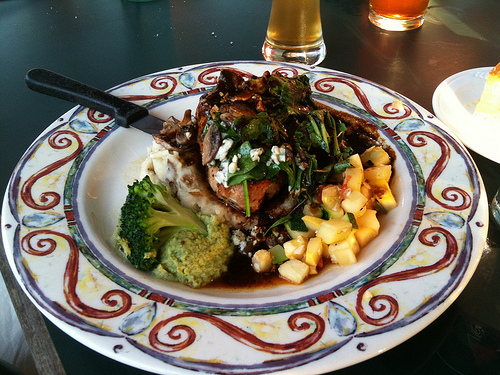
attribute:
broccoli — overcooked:
[115, 180, 210, 267]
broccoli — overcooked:
[157, 218, 234, 290]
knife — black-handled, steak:
[21, 61, 165, 143]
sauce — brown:
[211, 234, 286, 294]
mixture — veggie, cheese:
[112, 68, 397, 287]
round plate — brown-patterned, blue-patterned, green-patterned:
[55, 96, 364, 316]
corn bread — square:
[473, 60, 496, 127]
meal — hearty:
[72, 91, 413, 279]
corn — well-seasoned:
[341, 190, 368, 214]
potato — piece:
[317, 217, 354, 241]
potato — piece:
[329, 245, 353, 265]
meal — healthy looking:
[109, 64, 398, 296]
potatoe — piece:
[256, 247, 274, 269]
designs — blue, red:
[2, 53, 499, 373]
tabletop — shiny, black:
[91, 10, 213, 65]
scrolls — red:
[333, 61, 498, 348]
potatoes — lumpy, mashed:
[174, 169, 226, 216]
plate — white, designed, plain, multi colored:
[0, 58, 489, 374]